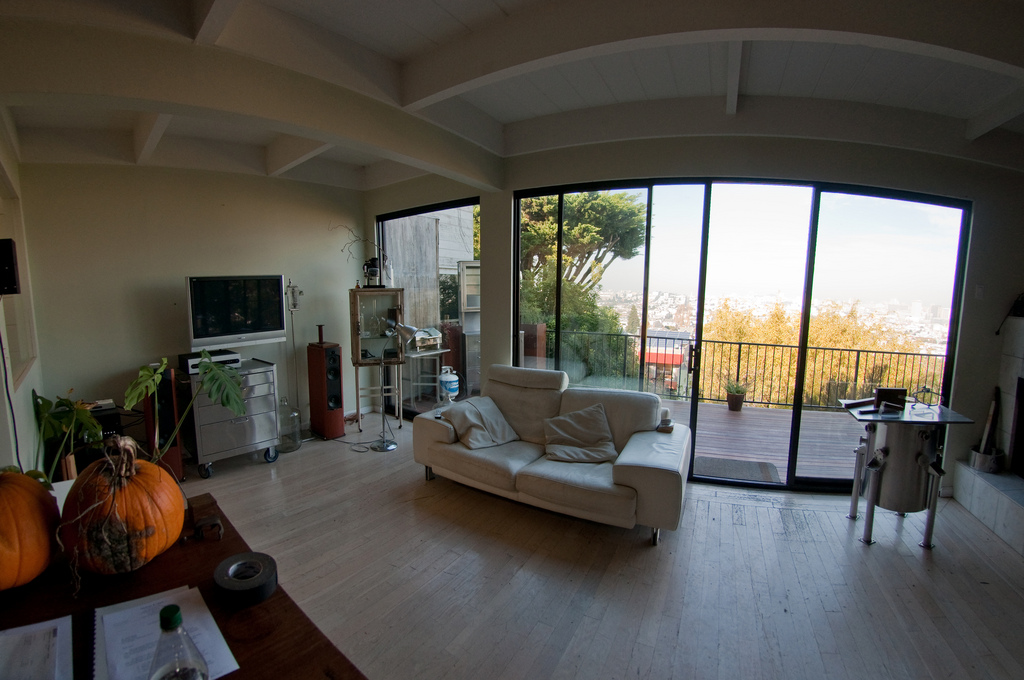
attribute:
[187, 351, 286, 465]
cabinet — silver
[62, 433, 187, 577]
pumpkin — orange, rotting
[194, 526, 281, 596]
tape — black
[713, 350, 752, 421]
plant — small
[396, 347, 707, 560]
loveseat — small, white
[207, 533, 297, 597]
tape — roll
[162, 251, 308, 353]
flatscreentelevision — flatscreen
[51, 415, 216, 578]
pumpkin — beginning to rot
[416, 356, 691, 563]
couch — white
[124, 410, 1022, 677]
floor — wood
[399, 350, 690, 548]
sofa — white, colored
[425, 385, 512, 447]
pillow — colored, white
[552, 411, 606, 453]
pillow — white, colored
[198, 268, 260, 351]
tv — large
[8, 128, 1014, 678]
room — plasma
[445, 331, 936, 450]
patio — wooden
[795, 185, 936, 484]
window — large , rectangular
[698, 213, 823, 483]
window — rectangular, large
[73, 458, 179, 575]
pumpkin — orange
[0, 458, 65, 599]
pumpkin — orange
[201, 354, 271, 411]
leaf — green, colored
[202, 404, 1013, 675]
flooring — light colored, wood